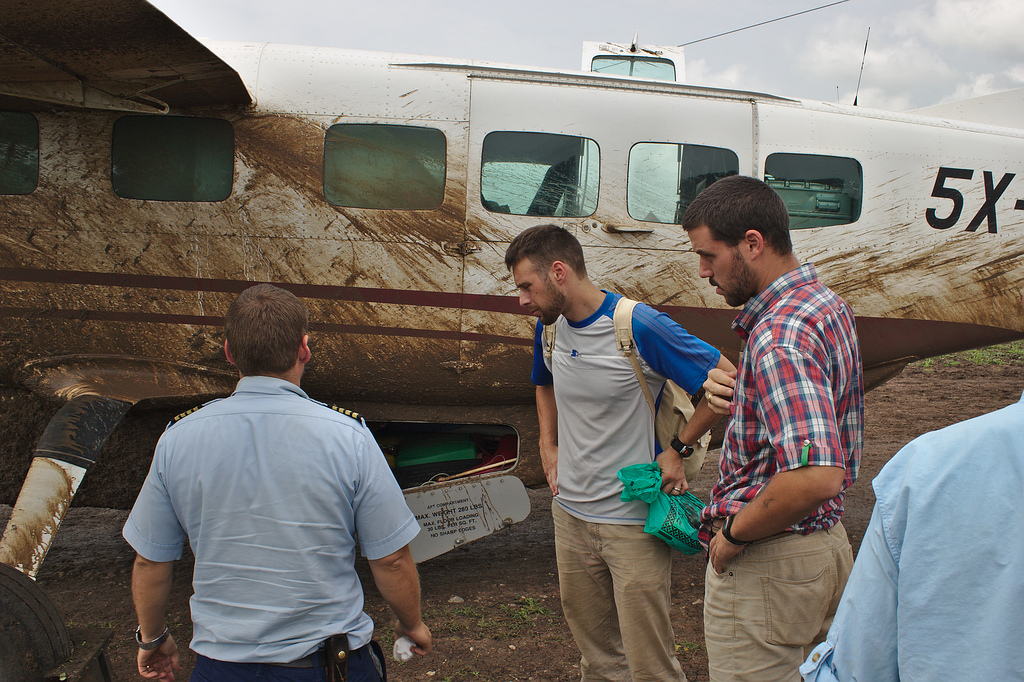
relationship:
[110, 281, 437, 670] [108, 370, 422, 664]
man in uniform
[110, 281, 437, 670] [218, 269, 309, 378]
man has hair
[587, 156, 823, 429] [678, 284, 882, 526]
man wearing shirt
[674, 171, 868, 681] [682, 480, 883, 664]
man wearing pants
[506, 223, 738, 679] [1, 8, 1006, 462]
man close to aircraft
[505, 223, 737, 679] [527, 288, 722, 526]
man in shirt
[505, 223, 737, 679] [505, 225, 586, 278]
man has hair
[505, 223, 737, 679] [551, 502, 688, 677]
man wearing pants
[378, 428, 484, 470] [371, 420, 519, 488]
luggages inside compartment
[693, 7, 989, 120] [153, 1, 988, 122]
cloud in sky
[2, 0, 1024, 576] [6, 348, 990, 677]
aircraft above surface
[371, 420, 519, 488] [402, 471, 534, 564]
compartment has door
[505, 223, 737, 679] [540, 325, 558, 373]
man with strap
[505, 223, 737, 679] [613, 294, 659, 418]
man with strap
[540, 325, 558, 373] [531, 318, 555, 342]
strap on shoulder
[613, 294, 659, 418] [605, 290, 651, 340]
strap on shoulder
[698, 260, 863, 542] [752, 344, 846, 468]
shirt with sleeves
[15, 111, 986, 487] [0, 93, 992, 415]
mud on side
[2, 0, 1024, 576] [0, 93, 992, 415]
aircraft has side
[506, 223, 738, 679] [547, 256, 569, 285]
man has a ear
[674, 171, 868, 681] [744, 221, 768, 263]
man has a ear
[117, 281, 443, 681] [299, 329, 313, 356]
man has a ear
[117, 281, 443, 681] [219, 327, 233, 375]
man has a ear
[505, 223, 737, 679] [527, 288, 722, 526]
man wearing shirt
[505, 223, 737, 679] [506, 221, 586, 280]
man with hair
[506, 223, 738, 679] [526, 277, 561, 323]
man with hair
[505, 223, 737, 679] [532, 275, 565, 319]
man with a beard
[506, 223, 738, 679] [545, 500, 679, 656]
man with pants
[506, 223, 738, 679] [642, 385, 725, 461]
man with backpack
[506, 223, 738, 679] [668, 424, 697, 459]
man with watch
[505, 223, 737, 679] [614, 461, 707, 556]
man with bag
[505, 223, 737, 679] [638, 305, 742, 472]
man with arms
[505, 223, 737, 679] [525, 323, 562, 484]
man with arms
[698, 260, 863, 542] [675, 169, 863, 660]
shirt the man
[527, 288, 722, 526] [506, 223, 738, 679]
shirt the man